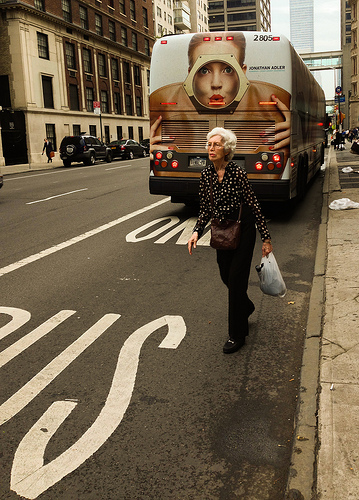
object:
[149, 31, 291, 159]
lady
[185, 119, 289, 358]
old woman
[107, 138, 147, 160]
car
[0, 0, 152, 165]
building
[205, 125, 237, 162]
hair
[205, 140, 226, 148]
glasses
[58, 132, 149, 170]
parked cars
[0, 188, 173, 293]
lines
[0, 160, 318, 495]
road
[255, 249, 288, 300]
bag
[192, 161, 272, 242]
shirt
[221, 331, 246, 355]
shoe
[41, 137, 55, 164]
man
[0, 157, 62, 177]
sidewalk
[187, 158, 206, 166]
license plate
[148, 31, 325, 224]
bus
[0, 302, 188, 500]
letters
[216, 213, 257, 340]
pants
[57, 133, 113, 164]
car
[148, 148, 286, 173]
lights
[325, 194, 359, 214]
trash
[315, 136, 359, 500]
sidewalk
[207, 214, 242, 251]
bag